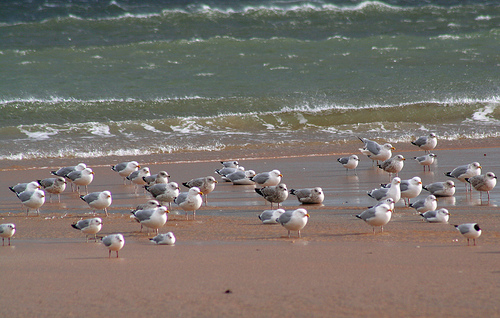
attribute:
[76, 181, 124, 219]
bird — grounded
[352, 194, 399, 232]
bird — grounded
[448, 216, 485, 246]
bird — grounded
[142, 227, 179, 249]
bird — grounded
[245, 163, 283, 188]
bird — grounded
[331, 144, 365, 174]
bird — grounded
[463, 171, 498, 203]
bird — gray and white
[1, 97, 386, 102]
water — white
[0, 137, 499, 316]
sand — wet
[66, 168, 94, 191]
bird — gray and white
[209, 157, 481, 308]
sand — wet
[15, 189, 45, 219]
bird — gray, white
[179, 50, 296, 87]
water's surface — choppy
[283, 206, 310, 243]
bird — gray, white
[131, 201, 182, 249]
bird — white, gray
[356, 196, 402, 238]
bird — white, gray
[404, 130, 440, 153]
bird — white, gray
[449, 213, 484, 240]
bird — white, gray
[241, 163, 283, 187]
seagull — gray and white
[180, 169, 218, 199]
bird — gray and white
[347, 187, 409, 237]
bird — gray and white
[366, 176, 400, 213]
birds — grounded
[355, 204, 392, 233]
birds — grounded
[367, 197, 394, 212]
birds — grounded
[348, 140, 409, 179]
bird — gray and white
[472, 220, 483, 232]
face — black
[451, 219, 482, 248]
bird — gray and white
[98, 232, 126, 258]
bird — gray, white